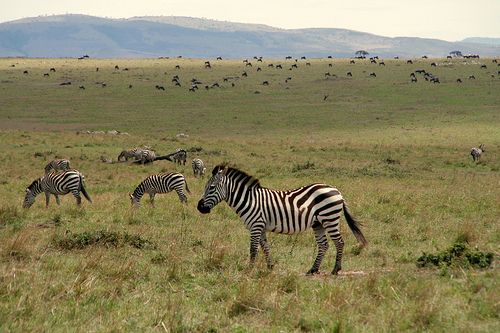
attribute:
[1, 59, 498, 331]
grass — green, brown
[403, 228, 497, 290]
bush — short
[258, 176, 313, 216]
stripes — black, white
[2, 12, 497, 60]
mountains — distant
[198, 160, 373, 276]
zebra — white, black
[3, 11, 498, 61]
mountain range — distant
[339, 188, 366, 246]
tail — long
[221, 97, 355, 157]
field — green